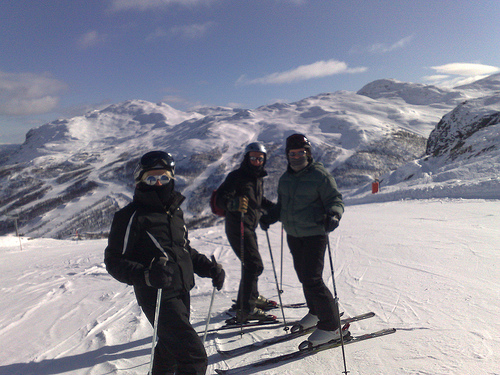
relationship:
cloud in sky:
[0, 0, 500, 146] [0, 0, 497, 143]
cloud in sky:
[0, 66, 64, 116] [0, 0, 497, 143]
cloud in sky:
[0, 0, 500, 146] [4, 1, 484, 189]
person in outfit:
[209, 143, 276, 323] [201, 155, 287, 308]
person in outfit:
[105, 151, 225, 375] [100, 181, 231, 370]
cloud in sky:
[260, 62, 349, 87] [24, 20, 477, 107]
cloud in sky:
[6, 69, 55, 113] [24, 20, 477, 107]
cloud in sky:
[0, 0, 500, 146] [24, 20, 477, 107]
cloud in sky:
[362, 38, 411, 53] [0, 6, 500, 135]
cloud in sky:
[232, 59, 367, 87] [0, 6, 500, 135]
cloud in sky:
[0, 0, 500, 146] [0, 6, 500, 135]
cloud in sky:
[0, 0, 500, 146] [4, 2, 484, 167]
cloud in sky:
[0, 0, 500, 146] [78, 5, 406, 69]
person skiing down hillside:
[259, 133, 344, 346] [7, 209, 478, 369]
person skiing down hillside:
[202, 124, 288, 335] [7, 209, 478, 369]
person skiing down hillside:
[105, 151, 225, 375] [7, 209, 478, 369]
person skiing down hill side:
[209, 143, 276, 323] [334, 221, 429, 313]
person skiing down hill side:
[273, 128, 358, 348] [334, 221, 429, 313]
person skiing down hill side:
[96, 140, 239, 366] [334, 221, 429, 313]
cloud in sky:
[0, 0, 500, 146] [3, 5, 490, 114]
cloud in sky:
[47, 26, 117, 56] [0, 0, 497, 143]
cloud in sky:
[102, 0, 217, 21] [0, 0, 497, 143]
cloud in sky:
[227, 52, 372, 89] [0, 0, 497, 143]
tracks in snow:
[4, 250, 153, 368] [3, 195, 493, 367]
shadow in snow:
[7, 335, 155, 372] [138, 287, 167, 361]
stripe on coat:
[119, 208, 141, 255] [98, 186, 211, 303]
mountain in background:
[189, 56, 450, 169] [4, 45, 494, 231]